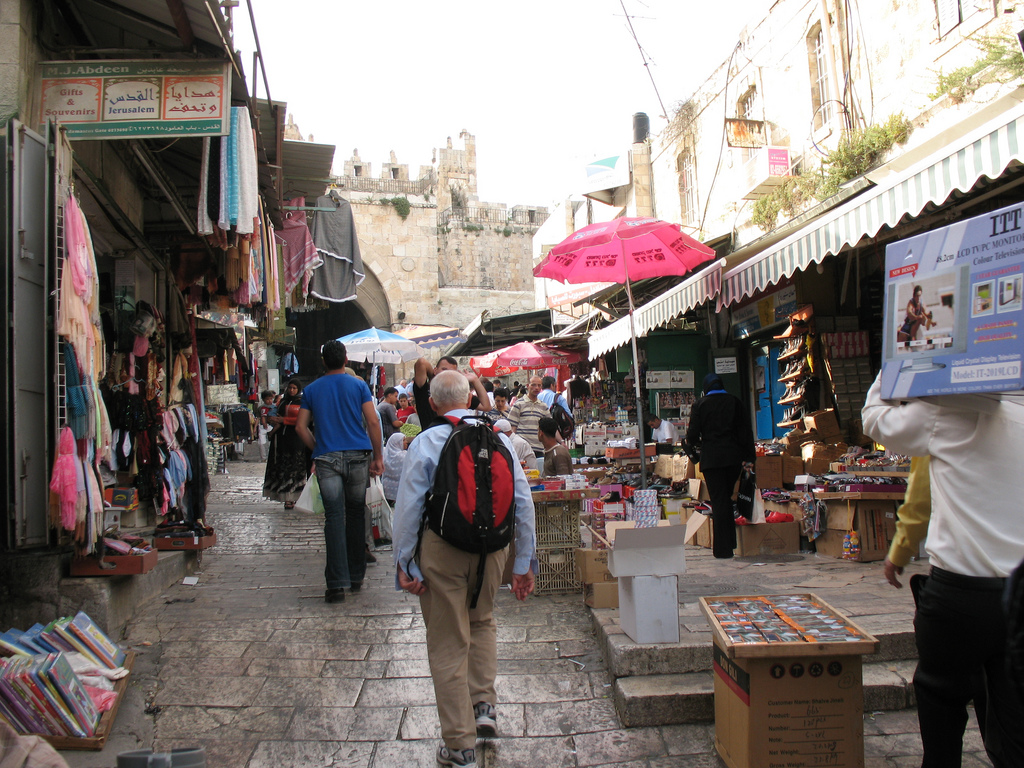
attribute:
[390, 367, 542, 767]
man — walking, older, old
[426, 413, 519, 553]
backback — red, black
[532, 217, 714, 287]
umbrella — pink, large, open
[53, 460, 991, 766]
street — brick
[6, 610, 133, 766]
items — for sale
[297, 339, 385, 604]
man — walking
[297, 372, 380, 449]
shirt — blue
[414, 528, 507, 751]
slacks — brown, khaki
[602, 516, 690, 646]
boxes — white, cardboard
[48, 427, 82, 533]
scarf — pink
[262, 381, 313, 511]
woman — walking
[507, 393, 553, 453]
shirt — striped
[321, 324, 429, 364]
umbrella — blue, white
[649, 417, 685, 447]
shirt — white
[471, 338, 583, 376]
umbrella — red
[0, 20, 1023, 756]
market — outdoor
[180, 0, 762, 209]
sky — overcast